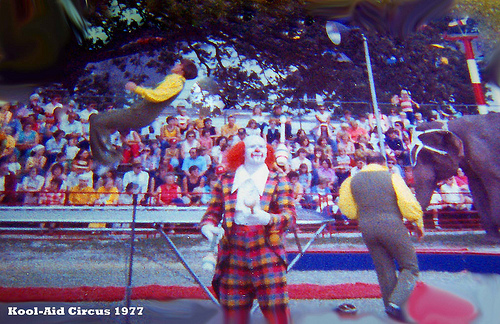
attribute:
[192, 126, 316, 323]
clown — male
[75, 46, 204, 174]
acrobat — jumping, turning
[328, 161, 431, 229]
shirt — long sleeve, yellow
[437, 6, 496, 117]
pole — red, white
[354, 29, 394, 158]
pole — light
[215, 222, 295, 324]
pants — plaid, checked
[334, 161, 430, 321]
clothing — grey, yellow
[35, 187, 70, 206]
shirt — red, white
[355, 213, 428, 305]
pants — grey